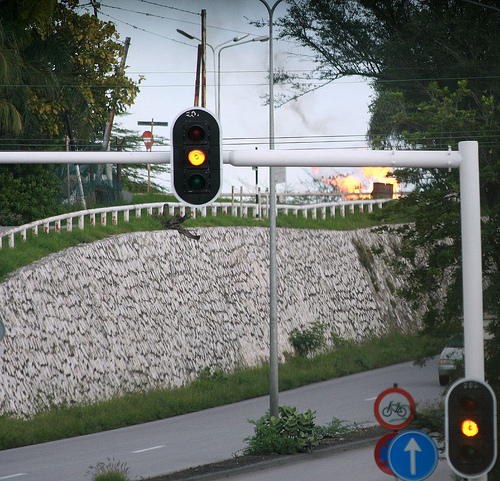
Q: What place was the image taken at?
A: It was taken at the road.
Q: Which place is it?
A: It is a road.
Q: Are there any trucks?
A: No, there are no trucks.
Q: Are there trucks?
A: No, there are no trucks.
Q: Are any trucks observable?
A: No, there are no trucks.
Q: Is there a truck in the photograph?
A: No, there are no trucks.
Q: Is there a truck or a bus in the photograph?
A: No, there are no trucks or buses.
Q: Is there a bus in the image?
A: No, there are no buses.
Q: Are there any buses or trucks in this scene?
A: No, there are no buses or trucks.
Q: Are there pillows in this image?
A: No, there are no pillows.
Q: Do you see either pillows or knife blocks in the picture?
A: No, there are no pillows or knife blocks.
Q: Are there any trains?
A: No, there are no trains.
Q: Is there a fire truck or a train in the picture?
A: No, there are no trains or fire trucks.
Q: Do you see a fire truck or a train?
A: No, there are no trains or fire trucks.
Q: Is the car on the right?
A: Yes, the car is on the right of the image.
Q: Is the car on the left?
A: No, the car is on the right of the image.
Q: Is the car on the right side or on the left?
A: The car is on the right of the image.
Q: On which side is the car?
A: The car is on the right of the image.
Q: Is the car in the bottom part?
A: Yes, the car is in the bottom of the image.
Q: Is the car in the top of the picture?
A: No, the car is in the bottom of the image.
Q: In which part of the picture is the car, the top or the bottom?
A: The car is in the bottom of the image.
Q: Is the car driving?
A: Yes, the car is driving.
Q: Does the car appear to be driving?
A: Yes, the car is driving.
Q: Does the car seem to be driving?
A: Yes, the car is driving.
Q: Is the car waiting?
A: No, the car is driving.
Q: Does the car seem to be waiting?
A: No, the car is driving.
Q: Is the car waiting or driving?
A: The car is driving.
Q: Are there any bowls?
A: No, there are no bowls.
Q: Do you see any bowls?
A: No, there are no bowls.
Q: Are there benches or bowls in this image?
A: No, there are no bowls or benches.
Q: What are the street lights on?
A: The street lights are on the pole.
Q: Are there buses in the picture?
A: No, there are no buses.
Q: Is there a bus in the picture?
A: No, there are no buses.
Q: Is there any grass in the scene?
A: Yes, there is grass.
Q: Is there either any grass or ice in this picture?
A: Yes, there is grass.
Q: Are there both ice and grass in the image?
A: No, there is grass but no ice.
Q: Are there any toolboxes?
A: No, there are no toolboxes.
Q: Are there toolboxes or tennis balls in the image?
A: No, there are no toolboxes or tennis balls.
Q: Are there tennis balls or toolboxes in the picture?
A: No, there are no toolboxes or tennis balls.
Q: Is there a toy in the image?
A: No, there are no toys.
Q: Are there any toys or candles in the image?
A: No, there are no toys or candles.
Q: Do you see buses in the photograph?
A: No, there are no buses.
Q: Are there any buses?
A: No, there are no buses.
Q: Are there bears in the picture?
A: No, there are no bears.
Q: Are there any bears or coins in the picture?
A: No, there are no bears or coins.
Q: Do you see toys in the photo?
A: No, there are no toys.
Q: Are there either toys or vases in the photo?
A: No, there are no toys or vases.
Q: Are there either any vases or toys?
A: No, there are no toys or vases.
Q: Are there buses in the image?
A: No, there are no buses.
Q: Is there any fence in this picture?
A: Yes, there is a fence.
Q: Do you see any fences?
A: Yes, there is a fence.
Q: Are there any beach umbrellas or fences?
A: Yes, there is a fence.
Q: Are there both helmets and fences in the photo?
A: No, there is a fence but no helmets.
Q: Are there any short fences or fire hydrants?
A: Yes, there is a short fence.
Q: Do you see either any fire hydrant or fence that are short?
A: Yes, the fence is short.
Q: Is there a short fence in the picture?
A: Yes, there is a short fence.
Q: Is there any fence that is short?
A: Yes, there is a fence that is short.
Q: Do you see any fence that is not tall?
A: Yes, there is a short fence.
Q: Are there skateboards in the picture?
A: No, there are no skateboards.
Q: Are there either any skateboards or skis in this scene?
A: No, there are no skateboards or skis.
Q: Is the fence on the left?
A: Yes, the fence is on the left of the image.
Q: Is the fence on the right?
A: No, the fence is on the left of the image.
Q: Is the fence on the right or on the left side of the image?
A: The fence is on the left of the image.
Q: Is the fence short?
A: Yes, the fence is short.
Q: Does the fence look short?
A: Yes, the fence is short.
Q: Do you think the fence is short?
A: Yes, the fence is short.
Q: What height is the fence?
A: The fence is short.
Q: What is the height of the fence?
A: The fence is short.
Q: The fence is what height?
A: The fence is short.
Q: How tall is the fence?
A: The fence is short.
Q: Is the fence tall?
A: No, the fence is short.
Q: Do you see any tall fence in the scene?
A: No, there is a fence but it is short.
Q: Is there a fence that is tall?
A: No, there is a fence but it is short.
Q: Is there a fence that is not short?
A: No, there is a fence but it is short.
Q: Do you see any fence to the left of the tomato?
A: Yes, there is a fence to the left of the tomato.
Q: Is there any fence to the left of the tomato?
A: Yes, there is a fence to the left of the tomato.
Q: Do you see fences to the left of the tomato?
A: Yes, there is a fence to the left of the tomato.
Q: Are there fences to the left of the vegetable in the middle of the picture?
A: Yes, there is a fence to the left of the tomato.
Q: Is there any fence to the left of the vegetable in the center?
A: Yes, there is a fence to the left of the tomato.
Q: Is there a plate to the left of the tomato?
A: No, there is a fence to the left of the tomato.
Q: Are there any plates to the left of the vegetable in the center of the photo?
A: No, there is a fence to the left of the tomato.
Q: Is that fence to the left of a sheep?
A: No, the fence is to the left of a tomato.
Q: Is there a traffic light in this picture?
A: Yes, there is a traffic light.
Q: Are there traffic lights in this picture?
A: Yes, there is a traffic light.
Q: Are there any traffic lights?
A: Yes, there is a traffic light.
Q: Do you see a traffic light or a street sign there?
A: Yes, there is a traffic light.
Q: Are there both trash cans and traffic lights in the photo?
A: No, there is a traffic light but no trash cans.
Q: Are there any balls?
A: No, there are no balls.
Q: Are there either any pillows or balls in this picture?
A: No, there are no balls or pillows.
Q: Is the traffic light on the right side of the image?
A: Yes, the traffic light is on the right of the image.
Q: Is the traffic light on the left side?
A: No, the traffic light is on the right of the image.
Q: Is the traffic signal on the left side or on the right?
A: The traffic signal is on the right of the image.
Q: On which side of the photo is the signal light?
A: The signal light is on the right of the image.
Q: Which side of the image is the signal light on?
A: The signal light is on the right of the image.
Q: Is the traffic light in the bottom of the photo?
A: Yes, the traffic light is in the bottom of the image.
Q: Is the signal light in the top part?
A: No, the signal light is in the bottom of the image.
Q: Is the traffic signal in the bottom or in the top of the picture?
A: The traffic signal is in the bottom of the image.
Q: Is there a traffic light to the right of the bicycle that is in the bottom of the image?
A: Yes, there is a traffic light to the right of the bicycle.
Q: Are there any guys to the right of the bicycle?
A: No, there is a traffic light to the right of the bicycle.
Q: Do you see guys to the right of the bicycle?
A: No, there is a traffic light to the right of the bicycle.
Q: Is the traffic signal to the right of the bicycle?
A: Yes, the traffic signal is to the right of the bicycle.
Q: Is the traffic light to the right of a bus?
A: No, the traffic light is to the right of the bicycle.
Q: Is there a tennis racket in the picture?
A: No, there are no rackets.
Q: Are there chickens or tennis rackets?
A: No, there are no tennis rackets or chickens.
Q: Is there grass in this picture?
A: Yes, there is grass.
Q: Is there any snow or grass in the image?
A: Yes, there is grass.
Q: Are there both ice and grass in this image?
A: No, there is grass but no ice.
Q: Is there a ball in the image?
A: No, there are no balls.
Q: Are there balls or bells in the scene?
A: No, there are no balls or bells.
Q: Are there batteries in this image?
A: No, there are no batteries.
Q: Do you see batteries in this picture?
A: No, there are no batteries.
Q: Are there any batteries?
A: No, there are no batteries.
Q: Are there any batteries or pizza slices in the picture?
A: No, there are no batteries or pizza slices.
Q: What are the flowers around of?
A: The flowers are around the pole.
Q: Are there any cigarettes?
A: No, there are no cigarettes.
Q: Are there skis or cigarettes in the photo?
A: No, there are no cigarettes or skis.